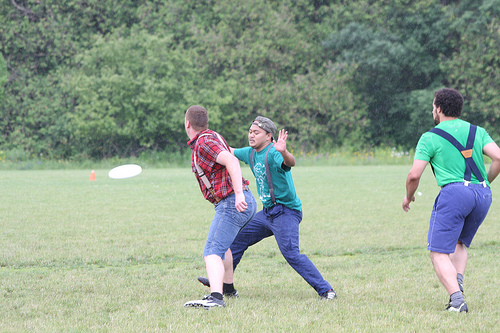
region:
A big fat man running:
[421, 65, 496, 322]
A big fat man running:
[172, 108, 244, 302]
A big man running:
[237, 94, 341, 331]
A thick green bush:
[92, 22, 176, 132]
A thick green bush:
[332, 21, 437, 131]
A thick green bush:
[205, 7, 335, 115]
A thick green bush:
[2, 16, 82, 145]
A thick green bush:
[457, 9, 498, 116]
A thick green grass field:
[32, 214, 145, 293]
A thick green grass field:
[307, 166, 411, 243]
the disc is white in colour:
[96, 150, 154, 181]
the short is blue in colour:
[431, 178, 497, 251]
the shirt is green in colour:
[404, 110, 486, 181]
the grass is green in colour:
[10, 220, 115, 332]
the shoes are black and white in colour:
[167, 290, 227, 312]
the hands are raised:
[217, 117, 312, 196]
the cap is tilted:
[246, 112, 286, 149]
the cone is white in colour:
[66, 143, 103, 183]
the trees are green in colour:
[56, 3, 181, 110]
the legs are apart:
[182, 172, 354, 332]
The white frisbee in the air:
[104, 160, 144, 184]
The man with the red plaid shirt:
[182, 100, 257, 308]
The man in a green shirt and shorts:
[394, 90, 499, 325]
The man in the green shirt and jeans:
[200, 113, 344, 303]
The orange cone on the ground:
[84, 165, 99, 183]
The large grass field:
[2, 165, 498, 331]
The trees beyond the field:
[0, 2, 499, 162]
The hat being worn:
[251, 111, 279, 136]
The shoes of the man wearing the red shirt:
[184, 285, 244, 308]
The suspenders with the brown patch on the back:
[428, 120, 485, 184]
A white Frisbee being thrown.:
[105, 161, 143, 177]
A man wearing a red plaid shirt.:
[181, 97, 256, 307]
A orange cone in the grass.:
[82, 165, 98, 180]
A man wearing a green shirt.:
[397, 81, 497, 311]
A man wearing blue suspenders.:
[400, 82, 495, 312]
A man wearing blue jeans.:
[195, 113, 337, 306]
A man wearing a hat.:
[194, 113, 338, 302]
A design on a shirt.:
[252, 160, 273, 205]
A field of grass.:
[0, 163, 499, 331]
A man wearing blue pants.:
[401, 84, 499, 317]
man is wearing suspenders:
[414, 113, 494, 193]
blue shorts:
[423, 170, 495, 255]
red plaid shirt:
[177, 135, 248, 205]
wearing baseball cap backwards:
[249, 108, 293, 142]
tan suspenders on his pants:
[174, 130, 255, 233]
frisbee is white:
[79, 119, 166, 187]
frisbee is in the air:
[98, 160, 139, 183]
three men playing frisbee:
[154, 102, 497, 307]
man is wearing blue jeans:
[235, 195, 338, 298]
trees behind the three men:
[42, 58, 375, 168]